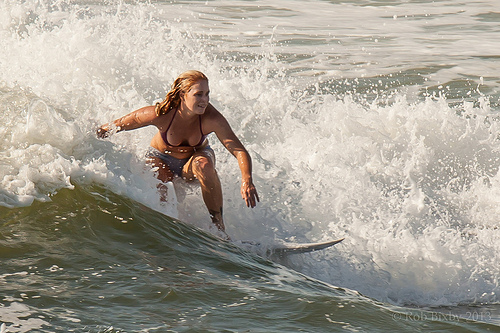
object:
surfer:
[94, 68, 260, 232]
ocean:
[0, 0, 499, 333]